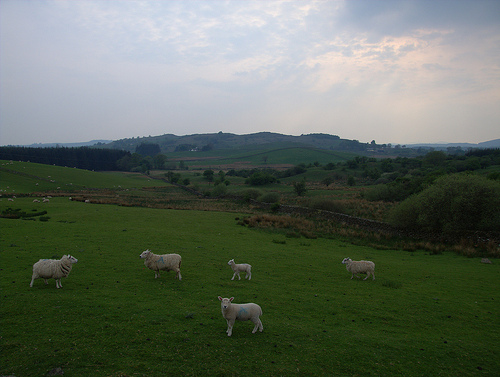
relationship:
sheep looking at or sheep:
[212, 288, 294, 343] [214, 250, 252, 276]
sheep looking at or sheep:
[212, 288, 294, 343] [339, 253, 383, 278]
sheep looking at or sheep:
[212, 288, 294, 343] [129, 242, 200, 280]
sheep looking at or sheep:
[212, 288, 294, 343] [25, 242, 78, 287]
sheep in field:
[218, 296, 264, 337] [0, 141, 497, 374]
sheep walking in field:
[15, 227, 357, 374] [0, 141, 497, 374]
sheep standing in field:
[26, 243, 378, 335] [0, 141, 497, 374]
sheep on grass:
[218, 296, 264, 337] [6, 160, 498, 370]